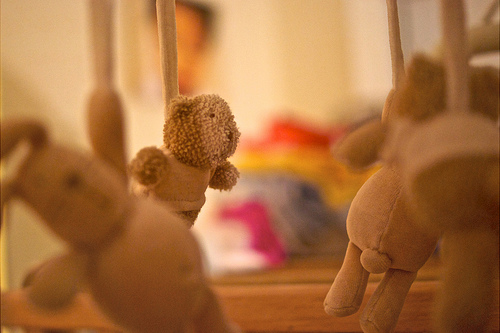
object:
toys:
[44, 81, 493, 313]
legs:
[310, 249, 416, 332]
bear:
[6, 117, 213, 332]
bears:
[13, 10, 232, 330]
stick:
[142, 8, 185, 109]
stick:
[376, 0, 414, 80]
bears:
[327, 51, 498, 324]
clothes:
[219, 107, 362, 278]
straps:
[80, 11, 482, 89]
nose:
[55, 164, 84, 191]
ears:
[2, 110, 54, 189]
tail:
[354, 246, 402, 275]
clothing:
[252, 115, 338, 149]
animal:
[322, 54, 492, 329]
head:
[158, 84, 243, 171]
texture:
[165, 84, 237, 177]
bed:
[234, 121, 365, 285]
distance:
[181, 51, 421, 280]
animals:
[4, 47, 494, 330]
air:
[7, 44, 496, 331]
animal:
[117, 80, 254, 223]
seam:
[378, 174, 411, 271]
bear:
[138, 94, 247, 222]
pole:
[149, 2, 196, 110]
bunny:
[12, 88, 240, 330]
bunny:
[306, 40, 458, 330]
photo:
[2, 4, 498, 329]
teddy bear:
[128, 93, 240, 226]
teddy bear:
[322, 52, 499, 332]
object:
[188, 113, 380, 275]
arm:
[126, 144, 169, 190]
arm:
[208, 163, 242, 190]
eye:
[206, 110, 218, 120]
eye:
[30, 168, 52, 187]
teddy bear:
[0, 85, 234, 331]